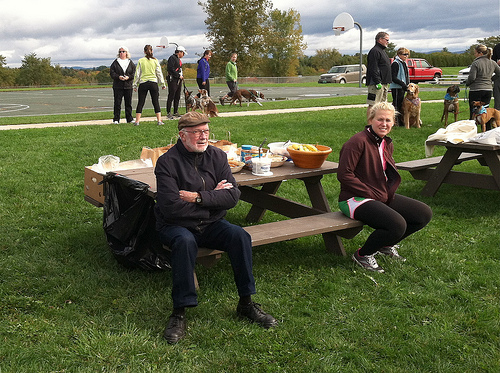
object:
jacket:
[225, 60, 239, 81]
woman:
[132, 45, 167, 126]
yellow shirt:
[132, 54, 166, 89]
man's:
[366, 31, 393, 124]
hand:
[178, 190, 201, 203]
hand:
[214, 179, 234, 190]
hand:
[123, 75, 130, 80]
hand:
[201, 82, 206, 86]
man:
[196, 50, 213, 99]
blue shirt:
[196, 58, 210, 82]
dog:
[224, 89, 265, 107]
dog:
[183, 88, 199, 113]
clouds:
[98, 5, 192, 36]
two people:
[153, 102, 433, 345]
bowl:
[287, 144, 333, 169]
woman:
[390, 48, 411, 127]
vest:
[389, 56, 411, 89]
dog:
[400, 83, 422, 129]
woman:
[336, 101, 433, 273]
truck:
[389, 57, 442, 84]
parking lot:
[258, 52, 500, 95]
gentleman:
[153, 111, 277, 345]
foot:
[236, 302, 278, 327]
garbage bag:
[102, 172, 160, 275]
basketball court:
[0, 12, 368, 118]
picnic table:
[83, 137, 366, 290]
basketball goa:
[331, 11, 363, 88]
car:
[318, 64, 368, 85]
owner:
[389, 47, 410, 127]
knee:
[221, 222, 253, 262]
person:
[219, 51, 239, 106]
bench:
[83, 159, 367, 294]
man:
[153, 110, 277, 345]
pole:
[359, 29, 363, 88]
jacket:
[337, 125, 402, 202]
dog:
[195, 89, 219, 118]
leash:
[176, 77, 195, 98]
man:
[166, 46, 189, 119]